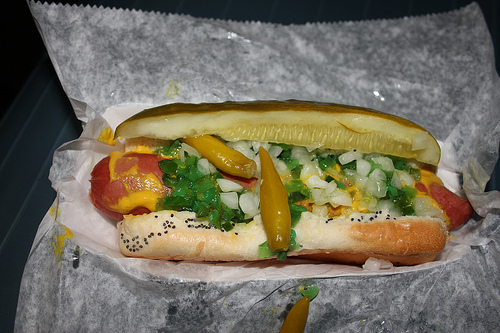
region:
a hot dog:
[91, 103, 472, 265]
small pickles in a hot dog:
[258, 148, 291, 256]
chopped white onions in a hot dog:
[178, 139, 417, 216]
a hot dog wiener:
[90, 150, 470, 235]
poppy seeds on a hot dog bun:
[118, 208, 397, 253]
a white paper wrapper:
[15, 0, 496, 332]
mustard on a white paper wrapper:
[45, 127, 116, 259]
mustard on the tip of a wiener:
[107, 141, 166, 211]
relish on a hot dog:
[157, 143, 420, 263]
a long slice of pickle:
[113, 98, 444, 163]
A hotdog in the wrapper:
[92, 98, 447, 264]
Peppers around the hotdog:
[186, 138, 311, 332]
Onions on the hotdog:
[296, 149, 351, 207]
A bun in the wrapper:
[118, 216, 446, 260]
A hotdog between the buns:
[88, 153, 469, 225]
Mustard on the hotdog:
[116, 193, 159, 211]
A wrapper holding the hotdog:
[15, 3, 499, 331]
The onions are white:
[294, 153, 343, 207]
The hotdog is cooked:
[88, 100, 473, 262]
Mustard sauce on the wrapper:
[50, 227, 70, 256]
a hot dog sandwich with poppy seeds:
[79, 103, 471, 266]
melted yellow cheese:
[102, 137, 157, 213]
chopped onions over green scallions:
[286, 135, 406, 216]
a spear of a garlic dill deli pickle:
[100, 95, 435, 162]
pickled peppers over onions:
[180, 135, 315, 325]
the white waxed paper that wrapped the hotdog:
[6, 0, 496, 330]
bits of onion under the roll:
[360, 247, 400, 272]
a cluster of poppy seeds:
[120, 215, 190, 255]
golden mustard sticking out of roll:
[100, 116, 445, 216]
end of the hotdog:
[419, 152, 469, 232]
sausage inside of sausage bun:
[54, 95, 486, 288]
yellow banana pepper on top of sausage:
[242, 143, 312, 262]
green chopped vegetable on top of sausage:
[158, 143, 419, 220]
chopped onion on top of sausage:
[176, 136, 427, 227]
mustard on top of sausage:
[111, 142, 168, 224]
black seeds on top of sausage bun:
[123, 215, 230, 257]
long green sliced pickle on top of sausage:
[113, 94, 450, 168]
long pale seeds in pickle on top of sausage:
[246, 122, 404, 152]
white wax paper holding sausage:
[11, 0, 493, 330]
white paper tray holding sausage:
[78, 89, 480, 308]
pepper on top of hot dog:
[256, 145, 299, 254]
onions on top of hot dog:
[339, 149, 388, 203]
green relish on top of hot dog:
[155, 151, 240, 233]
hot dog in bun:
[91, 151, 483, 228]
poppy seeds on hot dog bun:
[106, 207, 452, 270]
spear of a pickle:
[105, 96, 454, 176]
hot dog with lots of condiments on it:
[92, 95, 483, 280]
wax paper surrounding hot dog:
[16, 3, 498, 331]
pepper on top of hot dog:
[172, 123, 255, 183]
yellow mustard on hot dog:
[102, 151, 157, 215]